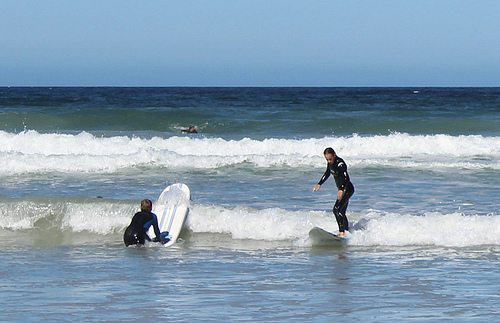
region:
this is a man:
[316, 140, 364, 221]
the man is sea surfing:
[298, 150, 359, 250]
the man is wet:
[321, 154, 356, 222]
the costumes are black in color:
[333, 153, 354, 216]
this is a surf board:
[163, 176, 193, 222]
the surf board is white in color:
[163, 186, 189, 218]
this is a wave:
[227, 197, 297, 242]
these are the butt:
[125, 222, 142, 242]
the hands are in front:
[306, 182, 349, 197]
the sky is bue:
[283, 12, 332, 59]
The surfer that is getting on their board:
[121, 178, 193, 260]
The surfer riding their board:
[297, 144, 361, 246]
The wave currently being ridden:
[3, 192, 499, 250]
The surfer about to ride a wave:
[174, 122, 203, 136]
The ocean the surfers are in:
[0, 85, 498, 322]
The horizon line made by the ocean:
[1, 84, 499, 91]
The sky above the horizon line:
[1, 1, 498, 86]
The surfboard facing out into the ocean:
[148, 181, 194, 247]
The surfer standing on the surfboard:
[312, 144, 360, 241]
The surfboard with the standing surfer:
[308, 219, 351, 246]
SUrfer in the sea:
[296, 142, 368, 251]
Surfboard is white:
[302, 221, 359, 257]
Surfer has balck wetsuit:
[303, 136, 375, 243]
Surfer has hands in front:
[293, 140, 370, 247]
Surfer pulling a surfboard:
[118, 189, 171, 257]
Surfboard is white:
[151, 171, 196, 253]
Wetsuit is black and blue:
[117, 193, 170, 253]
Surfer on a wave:
[172, 121, 210, 144]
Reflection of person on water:
[323, 251, 458, 321]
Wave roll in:
[7, 121, 492, 178]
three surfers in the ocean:
[95, 105, 415, 285]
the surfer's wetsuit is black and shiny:
[287, 139, 363, 254]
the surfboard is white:
[300, 217, 355, 253]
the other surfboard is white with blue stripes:
[130, 187, 202, 259]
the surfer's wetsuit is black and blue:
[114, 207, 164, 249]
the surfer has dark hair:
[315, 145, 340, 164]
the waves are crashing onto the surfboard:
[132, 184, 236, 226]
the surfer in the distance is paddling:
[163, 120, 213, 145]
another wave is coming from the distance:
[13, 99, 497, 129]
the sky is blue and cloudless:
[4, 5, 494, 93]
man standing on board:
[296, 126, 386, 268]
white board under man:
[167, 171, 206, 234]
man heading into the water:
[110, 169, 205, 274]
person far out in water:
[172, 104, 215, 155]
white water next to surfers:
[407, 129, 453, 174]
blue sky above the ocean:
[222, 13, 357, 78]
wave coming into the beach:
[253, 126, 290, 164]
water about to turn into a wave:
[106, 98, 161, 135]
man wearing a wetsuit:
[110, 196, 176, 281]